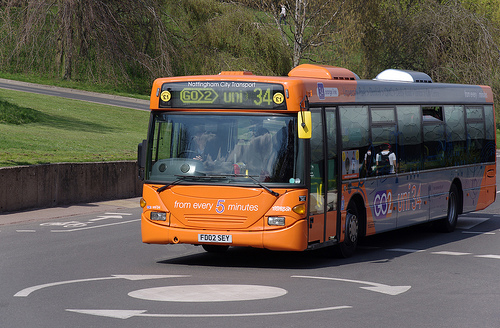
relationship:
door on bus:
[315, 96, 365, 232] [152, 71, 472, 255]